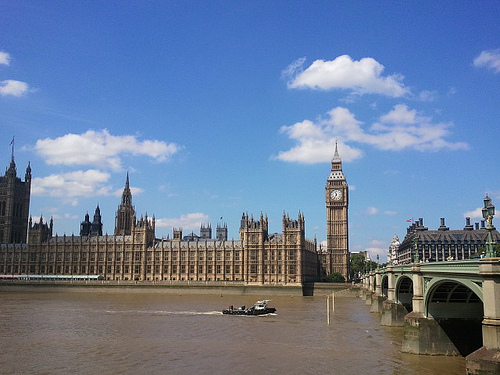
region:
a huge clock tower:
[293, 130, 378, 292]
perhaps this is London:
[24, 133, 496, 333]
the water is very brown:
[93, 321, 220, 365]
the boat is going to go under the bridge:
[213, 288, 285, 347]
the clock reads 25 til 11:
[319, 118, 366, 284]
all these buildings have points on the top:
[3, 123, 319, 313]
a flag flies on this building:
[398, 208, 434, 235]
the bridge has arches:
[360, 269, 498, 356]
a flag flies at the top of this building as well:
[6, 128, 26, 159]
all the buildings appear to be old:
[11, 148, 363, 318]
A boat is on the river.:
[220, 298, 276, 318]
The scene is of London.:
[0, 136, 499, 373]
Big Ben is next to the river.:
[322, 140, 348, 281]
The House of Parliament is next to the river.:
[1, 137, 323, 284]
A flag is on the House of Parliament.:
[4, 133, 21, 165]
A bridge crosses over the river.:
[354, 193, 499, 374]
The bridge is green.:
[353, 194, 498, 373]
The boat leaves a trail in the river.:
[70, 309, 223, 315]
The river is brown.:
[1, 294, 358, 373]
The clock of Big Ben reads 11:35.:
[327, 187, 343, 202]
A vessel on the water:
[207, 289, 286, 324]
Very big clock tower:
[316, 130, 361, 298]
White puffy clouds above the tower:
[217, 18, 477, 194]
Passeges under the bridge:
[353, 254, 492, 367]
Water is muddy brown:
[6, 285, 218, 371]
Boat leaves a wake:
[99, 299, 255, 324]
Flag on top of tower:
[7, 132, 21, 169]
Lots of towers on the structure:
[2, 128, 381, 239]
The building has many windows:
[3, 234, 330, 292]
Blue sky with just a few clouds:
[8, 5, 493, 247]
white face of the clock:
[328, 190, 344, 201]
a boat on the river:
[213, 295, 288, 325]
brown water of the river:
[82, 320, 339, 363]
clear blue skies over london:
[58, 13, 257, 99]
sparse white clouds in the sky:
[259, 36, 444, 163]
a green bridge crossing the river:
[349, 257, 494, 347]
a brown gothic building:
[0, 188, 308, 288]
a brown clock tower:
[309, 140, 361, 289]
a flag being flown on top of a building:
[400, 213, 422, 229]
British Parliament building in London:
[0, 171, 315, 286]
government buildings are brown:
[5, 153, 356, 296]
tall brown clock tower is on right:
[311, 146, 353, 315]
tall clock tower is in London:
[297, 142, 368, 299]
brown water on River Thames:
[18, 295, 371, 365]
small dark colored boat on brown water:
[207, 287, 282, 334]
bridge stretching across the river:
[342, 212, 494, 320]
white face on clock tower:
[325, 181, 342, 211]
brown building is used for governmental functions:
[5, 180, 320, 284]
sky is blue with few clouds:
[37, 5, 273, 202]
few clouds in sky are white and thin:
[40, 52, 420, 222]